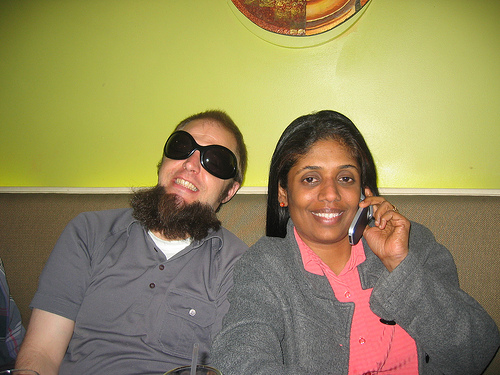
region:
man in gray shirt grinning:
[10, 106, 265, 371]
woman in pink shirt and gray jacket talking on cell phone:
[200, 105, 495, 370]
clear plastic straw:
[185, 340, 200, 370]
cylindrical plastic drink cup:
[156, 337, 228, 373]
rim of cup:
[0, 360, 60, 373]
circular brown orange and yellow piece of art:
[221, 0, 379, 40]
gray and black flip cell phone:
[343, 181, 378, 252]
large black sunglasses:
[161, 125, 252, 193]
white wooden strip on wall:
[0, 179, 499, 199]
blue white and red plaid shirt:
[0, 242, 34, 373]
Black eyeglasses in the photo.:
[205, 148, 239, 180]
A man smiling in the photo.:
[164, 171, 206, 201]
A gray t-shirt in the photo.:
[92, 261, 212, 343]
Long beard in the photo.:
[140, 197, 200, 229]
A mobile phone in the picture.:
[348, 214, 368, 244]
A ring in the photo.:
[387, 199, 397, 209]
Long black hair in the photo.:
[286, 113, 314, 156]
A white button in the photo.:
[184, 309, 203, 316]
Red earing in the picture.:
[277, 200, 285, 209]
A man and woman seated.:
[17, 107, 497, 374]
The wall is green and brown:
[12, 4, 492, 302]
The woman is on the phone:
[226, 109, 496, 369]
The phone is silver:
[346, 191, 375, 239]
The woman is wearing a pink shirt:
[217, 110, 496, 366]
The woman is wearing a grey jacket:
[223, 107, 497, 369]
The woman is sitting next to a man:
[25, 114, 487, 374]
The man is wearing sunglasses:
[128, 107, 254, 237]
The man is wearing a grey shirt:
[32, 109, 258, 373]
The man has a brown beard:
[126, 102, 245, 244]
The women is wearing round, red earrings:
[276, 195, 291, 215]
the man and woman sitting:
[12, 105, 499, 370]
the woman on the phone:
[229, 107, 496, 374]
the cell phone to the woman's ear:
[348, 190, 372, 245]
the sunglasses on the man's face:
[159, 128, 244, 190]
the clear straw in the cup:
[189, 340, 199, 373]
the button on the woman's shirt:
[343, 289, 351, 300]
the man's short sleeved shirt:
[34, 204, 248, 374]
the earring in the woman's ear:
[278, 202, 285, 208]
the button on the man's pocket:
[188, 308, 195, 316]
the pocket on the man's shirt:
[156, 288, 214, 360]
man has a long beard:
[150, 192, 208, 228]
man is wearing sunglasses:
[158, 120, 225, 174]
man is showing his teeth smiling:
[165, 174, 208, 201]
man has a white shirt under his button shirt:
[157, 224, 197, 269]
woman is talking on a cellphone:
[341, 179, 365, 252]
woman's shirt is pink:
[350, 307, 404, 365]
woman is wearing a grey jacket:
[295, 302, 378, 363]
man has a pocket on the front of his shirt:
[145, 291, 205, 348]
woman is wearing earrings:
[267, 196, 299, 211]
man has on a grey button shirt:
[100, 265, 161, 338]